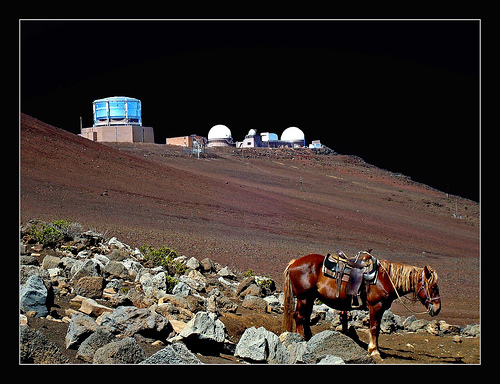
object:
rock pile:
[21, 225, 476, 375]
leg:
[365, 300, 385, 361]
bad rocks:
[20, 269, 52, 317]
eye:
[429, 284, 437, 294]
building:
[77, 124, 156, 144]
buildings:
[74, 93, 156, 147]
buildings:
[163, 132, 208, 148]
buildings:
[203, 121, 238, 148]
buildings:
[280, 126, 306, 147]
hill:
[22, 109, 477, 363]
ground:
[20, 154, 213, 181]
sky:
[21, 22, 482, 114]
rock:
[295, 327, 372, 364]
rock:
[143, 341, 208, 364]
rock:
[166, 309, 236, 343]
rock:
[72, 272, 105, 293]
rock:
[239, 295, 264, 310]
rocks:
[301, 326, 369, 363]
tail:
[280, 258, 294, 331]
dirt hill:
[12, 111, 467, 248]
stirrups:
[347, 290, 364, 309]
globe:
[205, 123, 232, 140]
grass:
[31, 217, 69, 245]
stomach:
[314, 288, 365, 310]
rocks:
[21, 322, 66, 363]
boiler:
[92, 91, 143, 125]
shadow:
[384, 343, 461, 360]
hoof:
[370, 349, 385, 362]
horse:
[273, 241, 450, 362]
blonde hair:
[365, 246, 440, 293]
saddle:
[310, 246, 388, 300]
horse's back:
[291, 240, 430, 320]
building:
[241, 126, 263, 148]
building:
[260, 130, 279, 145]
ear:
[423, 264, 431, 279]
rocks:
[123, 284, 157, 307]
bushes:
[149, 246, 168, 265]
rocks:
[169, 253, 188, 266]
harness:
[421, 291, 454, 316]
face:
[403, 262, 452, 321]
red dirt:
[130, 167, 347, 223]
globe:
[278, 121, 308, 143]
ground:
[20, 234, 479, 361]